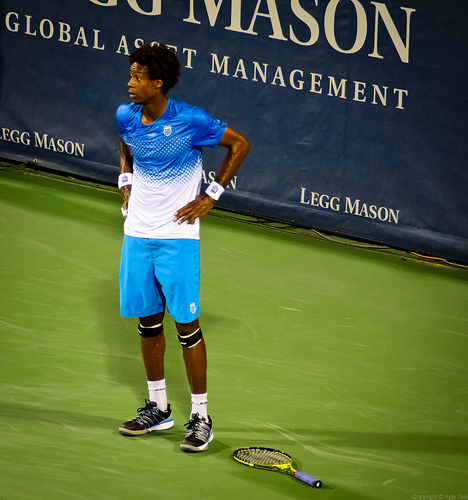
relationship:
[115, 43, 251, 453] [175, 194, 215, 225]
man has hand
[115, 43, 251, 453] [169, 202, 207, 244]
man has hip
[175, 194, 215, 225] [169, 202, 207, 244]
hand on hip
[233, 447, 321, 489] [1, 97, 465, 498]
racket laying on court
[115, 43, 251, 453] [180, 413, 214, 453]
man wearing shoe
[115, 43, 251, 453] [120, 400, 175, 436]
man wearing shoe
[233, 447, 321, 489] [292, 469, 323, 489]
racket has handle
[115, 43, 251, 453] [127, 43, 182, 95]
man has hair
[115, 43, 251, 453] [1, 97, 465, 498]
man standing on court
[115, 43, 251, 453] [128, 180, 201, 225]
man has waist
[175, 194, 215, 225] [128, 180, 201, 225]
hand on waist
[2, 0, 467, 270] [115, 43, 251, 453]
advertisement behind man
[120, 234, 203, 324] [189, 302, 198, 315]
shorts have logo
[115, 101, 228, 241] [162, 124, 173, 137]
shirt has logo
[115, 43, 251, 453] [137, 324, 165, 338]
man wearing knee band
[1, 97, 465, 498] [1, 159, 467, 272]
court has edge